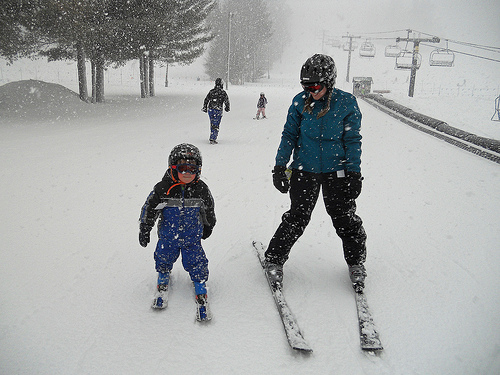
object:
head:
[298, 52, 338, 101]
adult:
[264, 50, 368, 297]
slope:
[0, 83, 499, 373]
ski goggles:
[299, 78, 329, 94]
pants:
[262, 167, 366, 267]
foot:
[348, 261, 368, 282]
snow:
[356, 290, 383, 349]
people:
[199, 77, 231, 145]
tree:
[0, 1, 222, 108]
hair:
[298, 84, 335, 120]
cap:
[168, 142, 203, 186]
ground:
[0, 78, 499, 373]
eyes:
[179, 166, 185, 170]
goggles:
[168, 156, 202, 175]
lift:
[426, 39, 456, 67]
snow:
[0, 80, 499, 374]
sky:
[285, 0, 500, 70]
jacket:
[273, 86, 362, 177]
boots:
[346, 262, 369, 283]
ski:
[251, 240, 316, 352]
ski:
[354, 283, 383, 351]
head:
[167, 141, 202, 184]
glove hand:
[271, 166, 289, 194]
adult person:
[199, 76, 232, 145]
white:
[41, 186, 77, 231]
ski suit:
[137, 167, 217, 282]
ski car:
[383, 45, 409, 61]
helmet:
[298, 50, 340, 90]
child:
[135, 142, 218, 295]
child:
[254, 90, 268, 120]